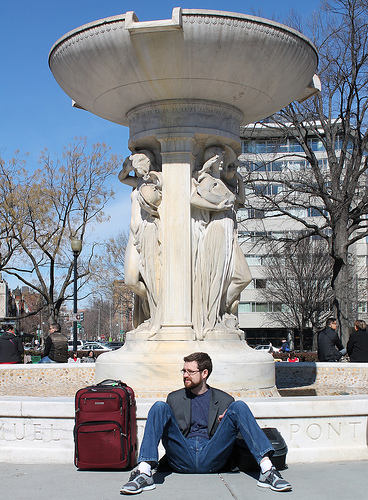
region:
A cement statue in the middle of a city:
[44, 3, 325, 396]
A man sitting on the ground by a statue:
[119, 350, 293, 496]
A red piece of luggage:
[68, 377, 139, 474]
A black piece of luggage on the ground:
[235, 426, 289, 472]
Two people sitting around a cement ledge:
[313, 315, 366, 358]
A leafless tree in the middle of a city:
[246, 3, 366, 361]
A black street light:
[68, 232, 84, 360]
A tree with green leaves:
[0, 130, 120, 321]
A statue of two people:
[117, 144, 261, 342]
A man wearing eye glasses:
[180, 351, 209, 391]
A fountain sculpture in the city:
[45, 7, 322, 356]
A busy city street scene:
[1, 299, 366, 361]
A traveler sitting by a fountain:
[64, 352, 298, 496]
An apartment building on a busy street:
[245, 124, 367, 360]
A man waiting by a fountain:
[121, 351, 291, 496]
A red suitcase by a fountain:
[70, 377, 139, 472]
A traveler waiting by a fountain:
[74, 346, 293, 499]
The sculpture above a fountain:
[118, 108, 251, 342]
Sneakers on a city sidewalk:
[114, 469, 295, 497]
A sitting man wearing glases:
[145, 351, 259, 480]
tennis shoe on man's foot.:
[122, 471, 152, 490]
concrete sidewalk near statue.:
[26, 470, 65, 497]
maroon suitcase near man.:
[77, 389, 125, 471]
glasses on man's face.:
[181, 368, 195, 374]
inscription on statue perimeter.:
[294, 424, 366, 433]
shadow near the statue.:
[283, 366, 318, 387]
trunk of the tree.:
[335, 259, 344, 316]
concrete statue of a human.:
[120, 157, 154, 294]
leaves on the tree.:
[27, 200, 50, 210]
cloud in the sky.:
[109, 203, 128, 230]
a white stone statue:
[42, 15, 289, 380]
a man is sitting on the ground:
[129, 342, 296, 496]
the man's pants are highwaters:
[118, 430, 359, 498]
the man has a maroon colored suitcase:
[62, 361, 134, 479]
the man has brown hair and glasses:
[174, 350, 222, 404]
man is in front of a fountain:
[120, 330, 281, 490]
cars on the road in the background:
[48, 304, 114, 357]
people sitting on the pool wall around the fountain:
[3, 307, 116, 366]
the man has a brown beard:
[141, 340, 252, 430]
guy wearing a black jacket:
[312, 295, 344, 390]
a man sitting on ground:
[120, 351, 291, 491]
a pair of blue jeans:
[136, 400, 276, 474]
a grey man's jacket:
[166, 385, 233, 434]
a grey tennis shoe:
[255, 465, 290, 490]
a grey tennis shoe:
[119, 468, 154, 493]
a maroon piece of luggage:
[72, 377, 135, 470]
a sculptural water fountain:
[3, 8, 367, 463]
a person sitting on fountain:
[318, 316, 342, 360]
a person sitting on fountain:
[347, 316, 367, 361]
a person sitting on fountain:
[36, 322, 68, 362]